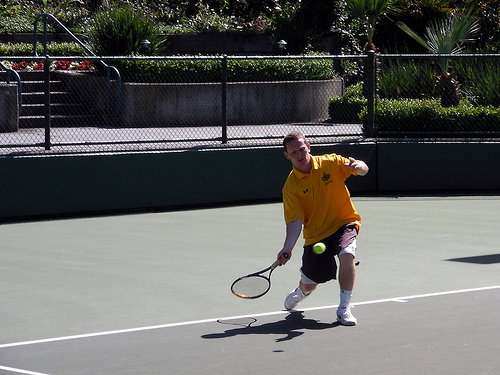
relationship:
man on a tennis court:
[276, 132, 369, 327] [4, 193, 498, 369]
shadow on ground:
[197, 309, 344, 352] [1, 196, 498, 374]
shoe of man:
[336, 305, 357, 326] [276, 130, 369, 326]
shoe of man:
[282, 286, 307, 312] [276, 130, 369, 326]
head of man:
[281, 129, 314, 172] [276, 130, 369, 326]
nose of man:
[293, 149, 306, 163] [276, 130, 369, 326]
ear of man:
[279, 147, 292, 164] [276, 130, 369, 326]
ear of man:
[306, 141, 311, 153] [276, 130, 369, 326]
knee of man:
[338, 246, 357, 266] [276, 130, 369, 326]